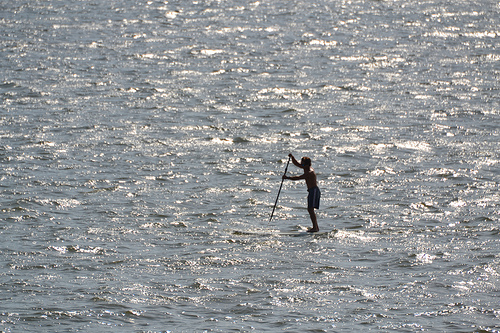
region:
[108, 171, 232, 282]
the water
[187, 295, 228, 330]
the water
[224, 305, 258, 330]
the water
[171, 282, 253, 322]
the water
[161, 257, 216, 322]
the water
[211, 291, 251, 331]
the water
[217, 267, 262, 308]
the water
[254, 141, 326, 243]
person on paddle board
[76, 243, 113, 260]
waves crashing in ocean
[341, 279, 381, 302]
waves crashing in ocean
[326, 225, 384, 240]
waves crashing in ocean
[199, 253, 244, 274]
waves crashing in ocean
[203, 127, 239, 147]
waves crashing in ocean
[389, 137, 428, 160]
waves crashing in ocean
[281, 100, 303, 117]
waves crashing in ocean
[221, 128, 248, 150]
waves crashing in ocean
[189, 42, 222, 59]
waves crashing in ocean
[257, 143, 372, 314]
Man paddle boarding in the ocean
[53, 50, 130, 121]
The water is flat with no waves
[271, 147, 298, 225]
The man is holding a stick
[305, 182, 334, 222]
He is wearing bathing suit bottoms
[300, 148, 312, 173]
The man has dark hair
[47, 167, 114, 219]
The light is reflecting off the water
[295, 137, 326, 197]
The man is not wearing a shirt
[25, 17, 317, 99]
There is nothing on top of the water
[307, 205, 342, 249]
The man is not wearing shoes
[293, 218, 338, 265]
The paddle board is floating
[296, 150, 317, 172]
the head of a man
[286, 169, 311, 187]
the arm of a man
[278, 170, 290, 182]
the hand of a man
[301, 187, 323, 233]
the leg of a man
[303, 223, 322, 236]
the foot of a man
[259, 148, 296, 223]
a black stick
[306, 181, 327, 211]
a pair of shorts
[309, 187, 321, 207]
a stripe on the shorts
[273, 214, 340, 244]
a board under the man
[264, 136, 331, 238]
a man on a board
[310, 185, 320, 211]
a vertical white stripe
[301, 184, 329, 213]
pair of blue and white shorts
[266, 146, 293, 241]
a long handled oar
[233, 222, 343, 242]
a white padle board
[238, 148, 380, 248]
a man standing on a board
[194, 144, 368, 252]
a man paddle boarding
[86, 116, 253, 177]
a few very small waves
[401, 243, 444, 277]
sun reflecting off the water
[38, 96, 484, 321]
a man surrounded by water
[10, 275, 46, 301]
ripples in the ocean